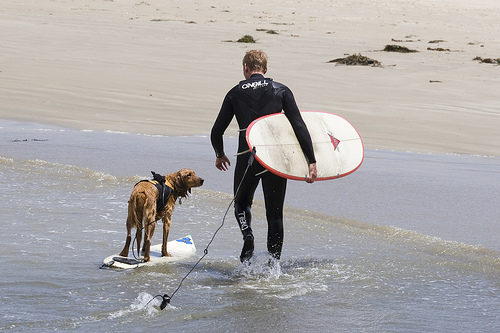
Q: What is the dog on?
A: Surf board.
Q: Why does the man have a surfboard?
A: To surf.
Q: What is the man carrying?
A: Surfboard.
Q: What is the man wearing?
A: A wetsuit.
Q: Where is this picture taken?
A: A beach.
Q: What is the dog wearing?
A: A life jacket.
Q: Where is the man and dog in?
A: The water.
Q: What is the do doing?
A: Surfing.